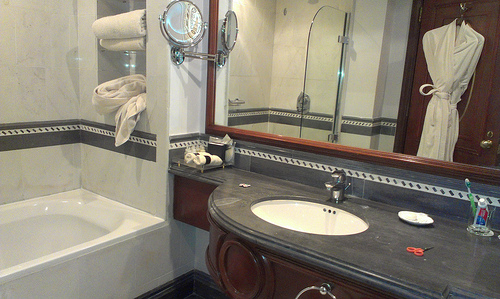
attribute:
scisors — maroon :
[381, 231, 430, 264]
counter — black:
[214, 159, 461, 276]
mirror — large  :
[213, 0, 498, 185]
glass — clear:
[469, 205, 495, 236]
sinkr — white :
[247, 179, 384, 251]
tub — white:
[1, 182, 182, 297]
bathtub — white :
[0, 185, 170, 297]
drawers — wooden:
[205, 206, 380, 297]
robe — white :
[417, 21, 487, 166]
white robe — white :
[409, 11, 494, 173]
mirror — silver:
[151, 0, 221, 69]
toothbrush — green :
[463, 176, 477, 218]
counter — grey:
[170, 157, 497, 298]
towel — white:
[84, 0, 165, 114]